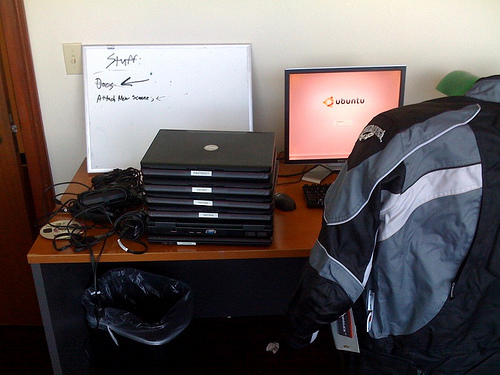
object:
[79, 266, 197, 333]
liner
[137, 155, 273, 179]
laptop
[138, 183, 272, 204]
laptop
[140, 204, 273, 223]
laptop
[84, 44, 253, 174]
board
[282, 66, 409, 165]
monitor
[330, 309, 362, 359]
computer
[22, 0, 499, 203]
wall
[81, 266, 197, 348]
can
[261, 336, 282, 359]
trash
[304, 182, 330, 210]
keyboard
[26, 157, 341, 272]
desk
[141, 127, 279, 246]
laptops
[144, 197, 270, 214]
laptop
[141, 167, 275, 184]
laptop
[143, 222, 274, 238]
laptop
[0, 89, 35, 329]
door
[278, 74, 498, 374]
jacket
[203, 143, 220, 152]
decal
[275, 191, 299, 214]
mouse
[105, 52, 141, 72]
stuff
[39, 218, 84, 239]
cd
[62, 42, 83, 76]
light switch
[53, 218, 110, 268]
wire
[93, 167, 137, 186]
wire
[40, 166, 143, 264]
cords